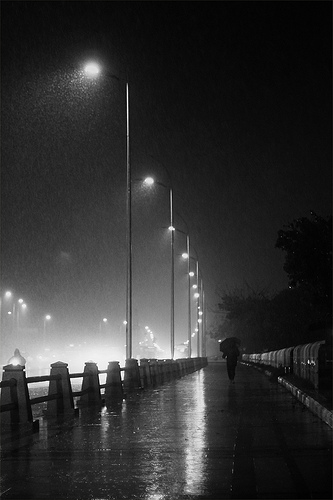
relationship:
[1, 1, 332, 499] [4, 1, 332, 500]
photo during nighttime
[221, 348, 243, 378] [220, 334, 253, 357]
person holding an umbrella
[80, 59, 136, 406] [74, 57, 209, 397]
streelamp on row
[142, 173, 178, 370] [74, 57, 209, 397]
streelamp on row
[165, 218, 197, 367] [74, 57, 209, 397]
streelamp on row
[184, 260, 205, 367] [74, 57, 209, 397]
streelamp on row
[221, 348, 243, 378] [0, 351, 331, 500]
person walking in sidewalk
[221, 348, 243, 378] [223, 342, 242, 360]
person has a hood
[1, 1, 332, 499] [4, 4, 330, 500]
photo at dark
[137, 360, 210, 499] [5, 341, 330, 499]
light on street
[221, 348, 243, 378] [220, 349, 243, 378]
person wearing coat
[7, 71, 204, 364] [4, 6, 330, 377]
mist into air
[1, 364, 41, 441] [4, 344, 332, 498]
column along bridge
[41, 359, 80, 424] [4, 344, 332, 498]
column along bridge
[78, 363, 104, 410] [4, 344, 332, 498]
column along bridge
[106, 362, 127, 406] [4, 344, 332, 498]
column along bridge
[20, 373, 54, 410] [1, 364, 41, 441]
pole between column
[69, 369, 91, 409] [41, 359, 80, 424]
pole between column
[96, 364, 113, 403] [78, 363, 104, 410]
pole between column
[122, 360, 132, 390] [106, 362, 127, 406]
pole between column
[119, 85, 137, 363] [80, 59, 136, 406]
metal pole supporting streelamp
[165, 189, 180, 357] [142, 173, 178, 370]
metal pole supporting streelamp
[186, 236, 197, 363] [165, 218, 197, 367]
metal pole supporting streelamp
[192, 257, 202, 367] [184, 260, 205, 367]
metal pole supporting streelamp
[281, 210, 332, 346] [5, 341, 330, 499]
tree over street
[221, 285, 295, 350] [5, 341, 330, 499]
tree over street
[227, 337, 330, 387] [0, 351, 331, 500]
cement riser on road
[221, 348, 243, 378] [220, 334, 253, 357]
person holding and umbrella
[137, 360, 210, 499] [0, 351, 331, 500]
light reflecting in sidewalk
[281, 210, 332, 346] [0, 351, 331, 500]
tree in side of sidewalk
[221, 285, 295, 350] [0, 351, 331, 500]
tree in side of sidewalk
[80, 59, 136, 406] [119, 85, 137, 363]
streelamp attached to metal pole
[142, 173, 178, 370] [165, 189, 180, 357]
streelamp attached to metal pole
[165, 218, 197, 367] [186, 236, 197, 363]
streelamp attached to metal pole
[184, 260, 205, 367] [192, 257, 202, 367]
streelamp attached to metal pole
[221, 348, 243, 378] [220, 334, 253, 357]
person holding umbrella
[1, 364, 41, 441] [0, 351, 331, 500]
column between sidewalk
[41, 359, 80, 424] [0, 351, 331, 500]
column between sidewalk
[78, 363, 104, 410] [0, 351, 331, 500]
column between sidewalk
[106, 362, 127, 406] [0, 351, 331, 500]
column between sidewalk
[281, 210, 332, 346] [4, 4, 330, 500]
tree in dark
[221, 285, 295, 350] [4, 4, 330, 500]
tree in dark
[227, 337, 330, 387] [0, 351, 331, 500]
cement riser next to sidewalk